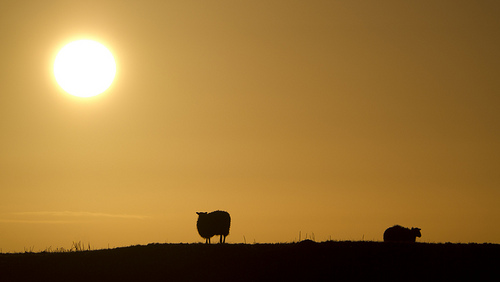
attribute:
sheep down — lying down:
[389, 207, 442, 254]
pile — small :
[293, 230, 318, 250]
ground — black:
[39, 28, 126, 110]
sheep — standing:
[192, 204, 237, 248]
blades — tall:
[21, 238, 96, 253]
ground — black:
[0, 239, 497, 280]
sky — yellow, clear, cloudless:
[3, 0, 498, 253]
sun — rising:
[46, 31, 127, 103]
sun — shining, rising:
[42, 30, 124, 107]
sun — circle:
[41, 30, 131, 99]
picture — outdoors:
[21, 27, 343, 271]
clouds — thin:
[6, 214, 182, 229]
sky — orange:
[2, 2, 497, 230]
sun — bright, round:
[50, 34, 120, 104]